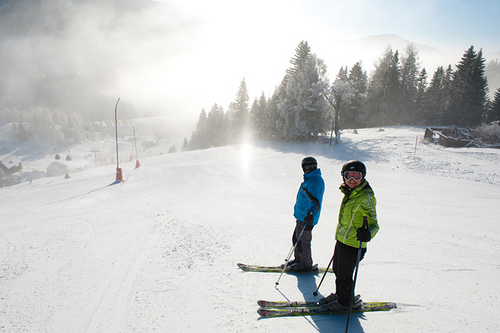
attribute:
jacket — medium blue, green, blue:
[293, 166, 326, 225]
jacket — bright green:
[335, 178, 380, 248]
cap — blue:
[301, 156, 319, 171]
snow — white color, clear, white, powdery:
[0, 124, 499, 332]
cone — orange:
[116, 167, 127, 184]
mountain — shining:
[354, 33, 443, 53]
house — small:
[0, 153, 24, 176]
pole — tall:
[114, 96, 122, 184]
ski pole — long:
[345, 214, 369, 332]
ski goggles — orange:
[342, 170, 364, 182]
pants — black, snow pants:
[332, 239, 367, 307]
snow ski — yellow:
[257, 304, 397, 318]